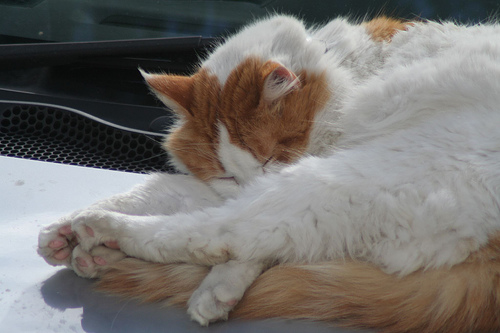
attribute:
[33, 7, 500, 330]
cat — fluffy, white, sleeping, orange, asleep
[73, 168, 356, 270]
legs — white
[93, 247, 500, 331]
tail — long, brown, white, orange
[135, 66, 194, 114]
ear — orange, brown, tan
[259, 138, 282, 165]
eye — closed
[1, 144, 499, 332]
table — mesh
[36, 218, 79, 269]
paw — white, pink